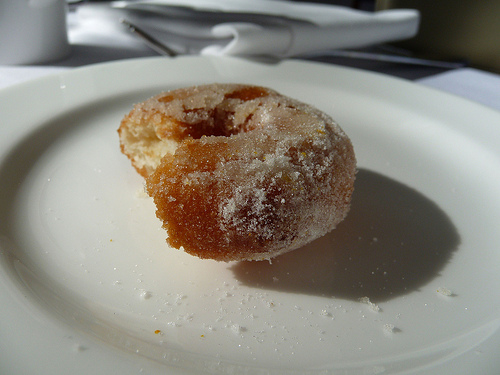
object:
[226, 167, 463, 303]
shadow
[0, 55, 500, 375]
white plate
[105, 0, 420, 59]
napkin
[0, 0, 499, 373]
plate table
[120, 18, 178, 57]
fork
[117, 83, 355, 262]
donut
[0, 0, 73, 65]
cup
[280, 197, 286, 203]
sugar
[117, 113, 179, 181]
bite